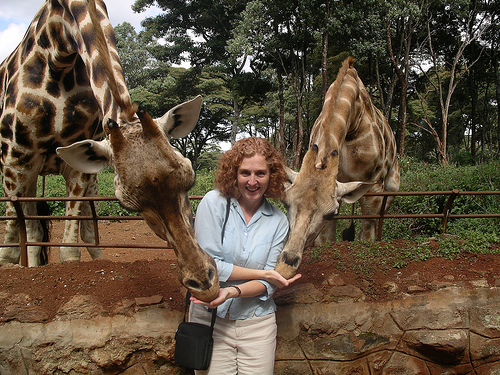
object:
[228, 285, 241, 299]
bracelet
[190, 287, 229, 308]
hand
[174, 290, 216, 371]
bag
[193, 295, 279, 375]
pants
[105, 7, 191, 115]
trees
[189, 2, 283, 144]
trees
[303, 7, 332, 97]
trees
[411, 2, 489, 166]
trees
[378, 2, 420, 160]
trees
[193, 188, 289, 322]
shirt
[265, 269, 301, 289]
hand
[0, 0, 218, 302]
giraffe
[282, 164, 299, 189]
ear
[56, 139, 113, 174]
ear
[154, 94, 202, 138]
ear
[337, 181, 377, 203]
ear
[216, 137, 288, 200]
curly hair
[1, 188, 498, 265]
fence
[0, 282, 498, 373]
stone wall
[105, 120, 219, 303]
head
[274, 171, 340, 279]
head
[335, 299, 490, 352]
rocks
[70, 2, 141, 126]
neck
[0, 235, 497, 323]
soil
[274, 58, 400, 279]
giraffe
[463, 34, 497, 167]
trees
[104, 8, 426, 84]
background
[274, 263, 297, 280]
mouth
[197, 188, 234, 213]
shoulder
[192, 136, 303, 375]
woman